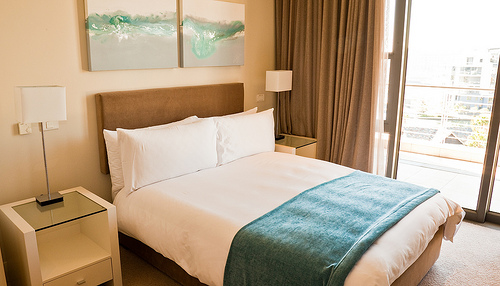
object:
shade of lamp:
[21, 87, 68, 122]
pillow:
[117, 119, 218, 193]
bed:
[97, 83, 463, 285]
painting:
[85, 0, 180, 69]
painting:
[180, 0, 247, 67]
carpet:
[120, 219, 498, 285]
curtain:
[275, 1, 385, 173]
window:
[396, 1, 495, 214]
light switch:
[18, 124, 33, 135]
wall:
[0, 1, 277, 206]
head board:
[95, 84, 247, 173]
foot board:
[391, 223, 444, 285]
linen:
[113, 151, 466, 285]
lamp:
[19, 87, 70, 206]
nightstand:
[0, 186, 123, 285]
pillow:
[216, 108, 276, 167]